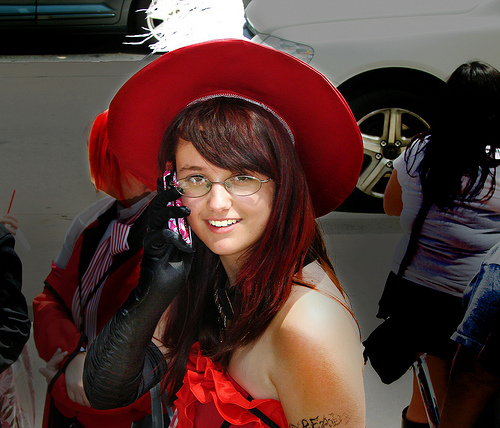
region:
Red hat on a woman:
[84, 69, 403, 269]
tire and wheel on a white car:
[330, 67, 453, 218]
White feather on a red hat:
[129, 1, 271, 66]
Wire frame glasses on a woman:
[162, 160, 290, 204]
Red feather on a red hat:
[70, 99, 155, 201]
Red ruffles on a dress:
[139, 326, 296, 423]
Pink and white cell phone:
[149, 166, 197, 268]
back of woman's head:
[430, 55, 497, 182]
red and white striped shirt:
[40, 229, 150, 329]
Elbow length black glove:
[75, 179, 201, 426]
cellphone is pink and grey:
[151, 161, 206, 253]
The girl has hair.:
[161, 125, 291, 171]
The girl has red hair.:
[205, 107, 280, 167]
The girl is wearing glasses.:
[172, 175, 267, 195]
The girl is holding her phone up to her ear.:
[155, 176, 195, 247]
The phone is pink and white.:
[155, 170, 187, 250]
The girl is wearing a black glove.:
[71, 215, 183, 405]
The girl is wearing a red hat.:
[106, 36, 361, 211]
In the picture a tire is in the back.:
[340, 67, 435, 204]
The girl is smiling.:
[197, 209, 254, 238]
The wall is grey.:
[7, 68, 84, 179]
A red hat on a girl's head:
[59, 46, 375, 239]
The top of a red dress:
[152, 328, 290, 425]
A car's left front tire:
[330, 68, 470, 221]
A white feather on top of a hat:
[155, 3, 247, 58]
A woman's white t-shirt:
[387, 139, 499, 251]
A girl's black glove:
[105, 190, 181, 426]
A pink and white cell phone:
[152, 154, 203, 249]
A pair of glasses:
[158, 148, 313, 228]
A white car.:
[218, 5, 492, 141]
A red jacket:
[42, 199, 186, 422]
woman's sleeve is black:
[81, 182, 188, 410]